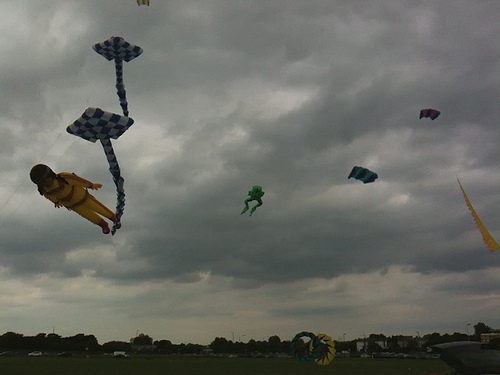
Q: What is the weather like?
A: Cloudy.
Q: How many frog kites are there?
A: 1.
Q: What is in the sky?
A: Kites.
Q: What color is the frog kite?
A: Green.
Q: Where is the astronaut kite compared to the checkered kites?
A: Below.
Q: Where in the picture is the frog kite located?
A: Center.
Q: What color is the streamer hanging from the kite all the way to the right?
A: Yellow.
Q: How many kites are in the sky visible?
A: 7.